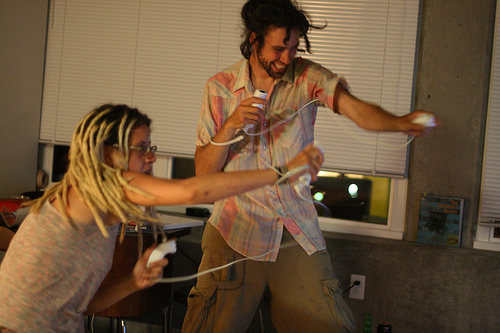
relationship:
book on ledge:
[416, 192, 465, 248] [30, 187, 499, 261]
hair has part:
[240, 2, 327, 60] [276, 23, 312, 49]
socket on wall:
[349, 274, 366, 301] [13, 250, 499, 332]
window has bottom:
[37, 1, 420, 243] [38, 134, 408, 245]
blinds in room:
[41, 0, 421, 183] [2, 3, 499, 330]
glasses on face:
[112, 141, 157, 156] [107, 125, 152, 177]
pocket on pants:
[180, 288, 213, 331] [182, 208, 360, 332]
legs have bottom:
[86, 306, 170, 333] [91, 317, 172, 332]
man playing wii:
[182, 1, 437, 332] [408, 112, 435, 137]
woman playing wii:
[2, 103, 322, 329] [145, 236, 177, 282]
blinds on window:
[41, 0, 421, 183] [37, 1, 420, 243]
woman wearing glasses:
[2, 103, 322, 329] [112, 141, 157, 156]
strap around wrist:
[270, 159, 308, 190] [269, 166, 295, 187]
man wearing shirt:
[182, 1, 437, 332] [202, 57, 347, 243]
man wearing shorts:
[182, 1, 437, 332] [182, 208, 360, 332]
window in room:
[37, 1, 420, 243] [2, 3, 499, 330]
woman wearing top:
[2, 103, 322, 329] [1, 181, 120, 332]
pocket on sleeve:
[180, 288, 213, 331] [196, 77, 238, 146]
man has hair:
[182, 1, 437, 332] [240, 2, 327, 60]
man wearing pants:
[182, 1, 437, 332] [182, 208, 360, 332]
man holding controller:
[182, 1, 437, 332] [246, 88, 267, 132]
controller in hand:
[246, 88, 267, 132] [226, 97, 268, 136]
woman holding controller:
[2, 103, 322, 329] [246, 88, 267, 132]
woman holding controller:
[2, 103, 322, 329] [295, 141, 325, 189]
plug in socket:
[353, 280, 362, 286] [349, 274, 366, 301]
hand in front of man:
[226, 97, 268, 136] [182, 1, 437, 332]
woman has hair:
[2, 103, 322, 329] [46, 102, 169, 239]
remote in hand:
[408, 112, 435, 137] [394, 106, 440, 138]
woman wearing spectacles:
[2, 103, 322, 329] [112, 141, 157, 156]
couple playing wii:
[3, 0, 440, 328] [408, 112, 435, 137]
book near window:
[416, 192, 465, 248] [37, 1, 420, 243]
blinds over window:
[41, 0, 421, 183] [37, 1, 420, 243]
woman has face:
[2, 103, 322, 329] [107, 125, 152, 177]